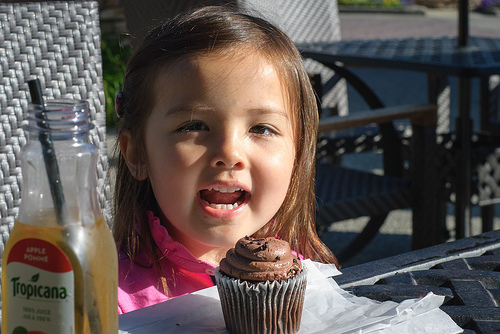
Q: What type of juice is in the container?
A: Apple Juice.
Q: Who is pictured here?
A: A Young Girl.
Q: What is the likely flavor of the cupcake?
A: Chocolate.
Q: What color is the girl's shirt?
A: Pink.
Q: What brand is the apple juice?
A: Tropicana.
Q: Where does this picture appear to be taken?
A: A Park.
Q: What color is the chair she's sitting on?
A: White.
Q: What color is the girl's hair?
A: Brown.